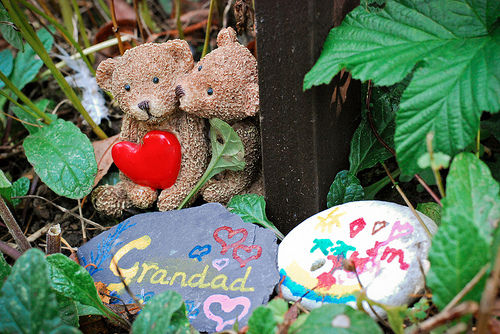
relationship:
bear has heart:
[83, 31, 230, 221] [110, 128, 180, 188]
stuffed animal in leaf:
[175, 23, 264, 208] [170, 116, 245, 211]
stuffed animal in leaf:
[90, 41, 203, 209] [170, 116, 245, 211]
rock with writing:
[75, 203, 279, 333] [108, 236, 256, 296]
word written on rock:
[103, 229, 253, 298] [75, 203, 279, 333]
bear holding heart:
[84, 35, 206, 212] [105, 125, 181, 194]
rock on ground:
[71, 197, 285, 329] [4, 204, 498, 325]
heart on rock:
[199, 290, 258, 332] [71, 197, 285, 329]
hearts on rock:
[208, 223, 265, 271] [71, 197, 285, 329]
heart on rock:
[187, 243, 211, 260] [71, 197, 285, 329]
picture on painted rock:
[305, 210, 409, 293] [276, 200, 438, 322]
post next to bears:
[253, 0, 340, 242] [89, 24, 263, 219]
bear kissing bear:
[84, 35, 206, 212] [173, 25, 261, 203]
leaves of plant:
[21, 109, 129, 222] [307, 0, 484, 308]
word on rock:
[98, 232, 253, 303] [71, 197, 285, 329]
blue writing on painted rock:
[78, 225, 129, 256] [276, 200, 438, 322]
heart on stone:
[212, 227, 243, 247] [85, 187, 308, 331]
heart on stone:
[234, 247, 255, 267] [85, 187, 308, 331]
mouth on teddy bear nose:
[135, 111, 164, 123] [136, 99, 151, 114]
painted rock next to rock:
[276, 200, 438, 322] [75, 203, 279, 333]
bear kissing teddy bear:
[175, 26, 264, 212] [93, 40, 200, 215]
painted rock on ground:
[276, 200, 438, 322] [2, 2, 497, 332]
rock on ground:
[75, 203, 279, 333] [2, 2, 497, 332]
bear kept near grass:
[90, 38, 208, 218] [0, 4, 91, 154]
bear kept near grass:
[175, 26, 264, 212] [0, 4, 91, 154]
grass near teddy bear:
[2, 1, 224, 137] [174, 28, 263, 207]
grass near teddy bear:
[2, 1, 224, 137] [90, 50, 209, 216]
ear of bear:
[215, 22, 235, 44] [180, 25, 279, 202]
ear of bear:
[239, 81, 260, 119] [180, 25, 279, 202]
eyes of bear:
[190, 55, 212, 96] [90, 23, 264, 213]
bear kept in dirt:
[90, 38, 208, 218] [4, 92, 135, 263]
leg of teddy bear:
[91, 168, 141, 222] [90, 50, 209, 216]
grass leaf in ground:
[26, 0, 102, 83] [3, 1, 261, 242]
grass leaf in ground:
[6, 2, 108, 138] [3, 1, 261, 242]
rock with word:
[71, 197, 285, 329] [103, 229, 253, 298]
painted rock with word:
[276, 200, 438, 322] [307, 234, 411, 270]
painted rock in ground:
[276, 200, 438, 322] [18, 139, 73, 312]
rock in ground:
[71, 197, 285, 329] [18, 139, 73, 312]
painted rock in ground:
[276, 200, 438, 322] [10, 193, 104, 315]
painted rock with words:
[276, 200, 438, 322] [117, 220, 239, 310]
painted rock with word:
[276, 200, 438, 322] [300, 231, 415, 273]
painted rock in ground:
[276, 200, 438, 322] [2, 2, 497, 332]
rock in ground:
[71, 197, 285, 329] [2, 2, 497, 332]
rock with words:
[71, 197, 285, 329] [108, 230, 253, 305]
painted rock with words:
[276, 200, 438, 322] [304, 231, 405, 278]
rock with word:
[71, 197, 285, 329] [103, 233, 256, 308]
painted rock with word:
[276, 200, 438, 322] [103, 229, 253, 298]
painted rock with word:
[276, 200, 438, 322] [306, 234, 417, 272]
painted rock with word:
[276, 200, 438, 322] [106, 233, 252, 296]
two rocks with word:
[135, 202, 285, 304] [103, 229, 253, 298]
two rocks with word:
[135, 202, 285, 304] [307, 237, 410, 275]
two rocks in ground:
[135, 202, 285, 304] [2, 2, 497, 332]